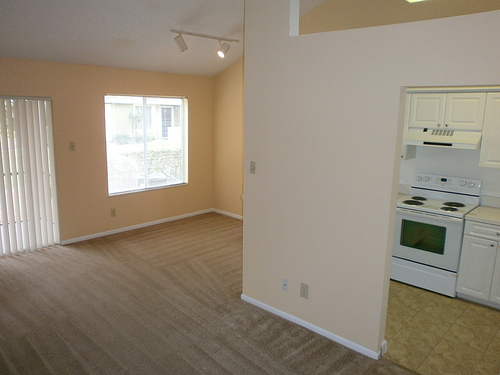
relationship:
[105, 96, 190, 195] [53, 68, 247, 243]
window on wall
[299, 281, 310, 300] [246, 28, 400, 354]
electrical socket on wall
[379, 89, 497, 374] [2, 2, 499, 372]
doorway in room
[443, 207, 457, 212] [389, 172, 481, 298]
burner on oven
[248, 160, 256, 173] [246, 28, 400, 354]
light switch on wall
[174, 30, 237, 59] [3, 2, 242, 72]
ceiling lights on ceiling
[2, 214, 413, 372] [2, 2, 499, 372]
carpet in room